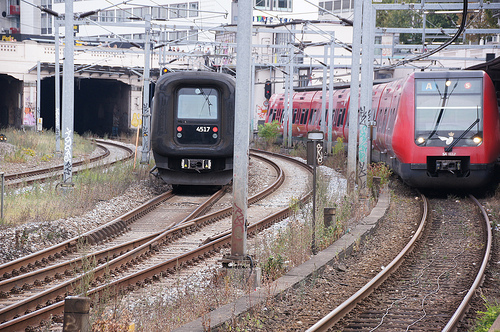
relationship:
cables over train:
[6, 3, 499, 66] [261, 68, 499, 182]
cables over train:
[6, 3, 499, 66] [147, 66, 243, 196]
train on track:
[263, 64, 498, 198] [301, 188, 495, 330]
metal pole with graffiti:
[219, 0, 256, 265] [233, 202, 243, 241]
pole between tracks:
[306, 129, 327, 255] [1, 145, 313, 330]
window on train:
[406, 63, 495, 143] [377, 74, 487, 195]